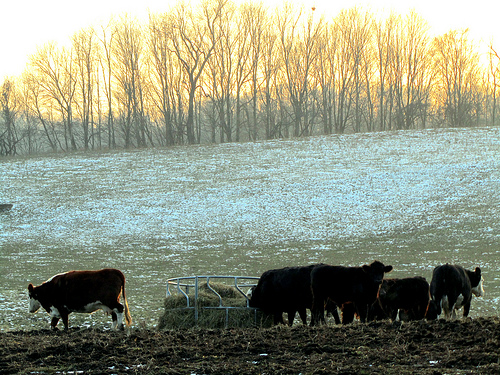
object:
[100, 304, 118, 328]
legs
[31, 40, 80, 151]
tree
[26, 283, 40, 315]
head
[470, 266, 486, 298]
head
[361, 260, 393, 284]
head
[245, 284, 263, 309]
head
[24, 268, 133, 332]
cow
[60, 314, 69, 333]
legs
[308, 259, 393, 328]
cow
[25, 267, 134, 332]
cow walking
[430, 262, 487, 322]
cow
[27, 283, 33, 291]
ear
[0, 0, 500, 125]
blue sky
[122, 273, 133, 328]
tail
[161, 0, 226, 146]
tree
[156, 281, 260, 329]
hay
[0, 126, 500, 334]
hill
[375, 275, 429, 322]
cow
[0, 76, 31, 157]
tree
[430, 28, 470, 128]
trees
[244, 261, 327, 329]
cow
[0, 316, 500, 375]
beach